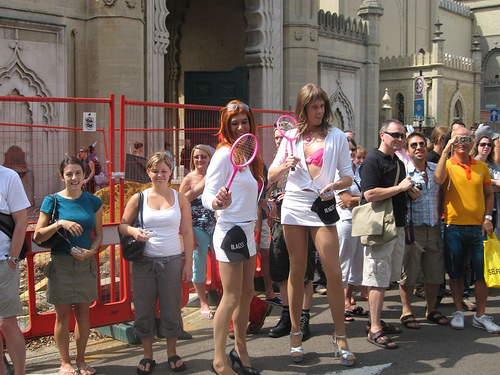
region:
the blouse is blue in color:
[58, 205, 95, 240]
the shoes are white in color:
[288, 328, 311, 360]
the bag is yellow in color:
[479, 236, 499, 290]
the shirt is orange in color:
[448, 163, 485, 220]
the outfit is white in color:
[219, 145, 263, 254]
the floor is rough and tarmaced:
[404, 335, 499, 370]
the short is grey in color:
[141, 265, 185, 333]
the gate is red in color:
[116, 95, 215, 137]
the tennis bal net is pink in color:
[228, 133, 265, 180]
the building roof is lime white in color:
[287, 20, 394, 71]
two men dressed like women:
[193, 61, 388, 373]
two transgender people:
[199, 78, 358, 370]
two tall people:
[207, 72, 367, 372]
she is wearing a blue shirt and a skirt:
[31, 150, 125, 371]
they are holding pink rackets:
[204, 55, 374, 370]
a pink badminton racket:
[221, 120, 263, 231]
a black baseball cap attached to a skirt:
[219, 211, 262, 278]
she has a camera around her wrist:
[51, 215, 93, 260]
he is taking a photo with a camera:
[439, 118, 495, 360]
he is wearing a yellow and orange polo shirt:
[436, 120, 499, 293]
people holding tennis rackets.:
[222, 112, 302, 198]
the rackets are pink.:
[220, 111, 302, 199]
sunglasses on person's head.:
[221, 102, 251, 113]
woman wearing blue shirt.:
[34, 185, 104, 254]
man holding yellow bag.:
[476, 225, 497, 288]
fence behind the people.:
[1, 87, 316, 334]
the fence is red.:
[2, 77, 304, 341]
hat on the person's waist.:
[217, 222, 253, 264]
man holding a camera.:
[451, 130, 472, 148]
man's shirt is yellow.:
[438, 156, 489, 232]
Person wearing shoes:
[206, 345, 263, 372]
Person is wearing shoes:
[210, 350, 260, 372]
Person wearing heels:
[202, 345, 258, 370]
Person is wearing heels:
[205, 340, 260, 370]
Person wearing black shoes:
[206, 345, 266, 371]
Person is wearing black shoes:
[207, 349, 263, 374]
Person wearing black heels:
[207, 345, 263, 373]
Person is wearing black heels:
[205, 346, 263, 373]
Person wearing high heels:
[207, 345, 262, 374]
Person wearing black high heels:
[207, 343, 258, 373]